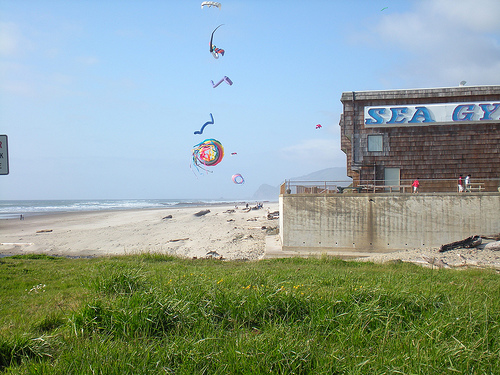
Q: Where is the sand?
A: Beach.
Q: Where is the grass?
A: Along the beach.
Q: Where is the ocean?
A: In front of sand.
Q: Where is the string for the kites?
A: Attached to the kites.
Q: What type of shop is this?
A: Sea shop.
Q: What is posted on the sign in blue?
A: SEA GY.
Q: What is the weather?
A: Partly cloudy.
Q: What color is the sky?
A: Blue and White.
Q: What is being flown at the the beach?
A: Kites.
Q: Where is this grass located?
A: In front of the sand.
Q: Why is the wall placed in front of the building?
A: To keep the water from flooding the building.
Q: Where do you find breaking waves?
A: At the beach.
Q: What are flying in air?
A: Kites.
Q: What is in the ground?
A: Grass.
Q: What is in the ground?
A: Fence.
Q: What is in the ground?
A: Sand.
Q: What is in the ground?
A: Grass.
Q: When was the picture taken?
A: Daytime.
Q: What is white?
A: Clouds.